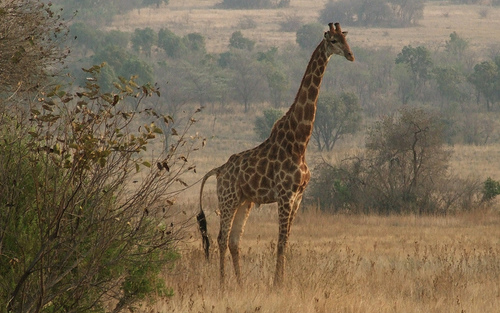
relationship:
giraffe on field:
[197, 21, 354, 287] [9, 1, 498, 310]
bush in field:
[1, 62, 203, 312] [117, 214, 498, 306]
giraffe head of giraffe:
[323, 22, 355, 62] [197, 21, 354, 287]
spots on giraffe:
[230, 158, 288, 193] [197, 21, 354, 287]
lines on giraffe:
[216, 151, 326, 209] [195, 17, 389, 287]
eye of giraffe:
[330, 38, 340, 44] [197, 21, 354, 287]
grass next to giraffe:
[187, 246, 352, 311] [197, 21, 354, 287]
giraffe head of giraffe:
[315, 20, 358, 67] [189, 10, 365, 295]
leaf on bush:
[163, 160, 170, 172] [7, 62, 189, 311]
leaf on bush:
[140, 159, 152, 167] [7, 62, 189, 311]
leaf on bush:
[163, 195, 180, 210] [7, 62, 189, 311]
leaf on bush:
[109, 92, 120, 105] [7, 62, 189, 311]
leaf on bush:
[192, 103, 206, 114] [7, 62, 189, 311]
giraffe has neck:
[196, 21, 355, 292] [265, 37, 322, 165]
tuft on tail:
[195, 208, 212, 265] [195, 164, 217, 259]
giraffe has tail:
[196, 21, 355, 292] [195, 164, 217, 259]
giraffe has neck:
[197, 21, 354, 287] [230, 45, 352, 135]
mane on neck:
[276, 33, 328, 123] [230, 45, 352, 135]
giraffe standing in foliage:
[196, 21, 355, 292] [10, 15, 190, 311]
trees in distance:
[136, 25, 274, 111] [29, 12, 483, 122]